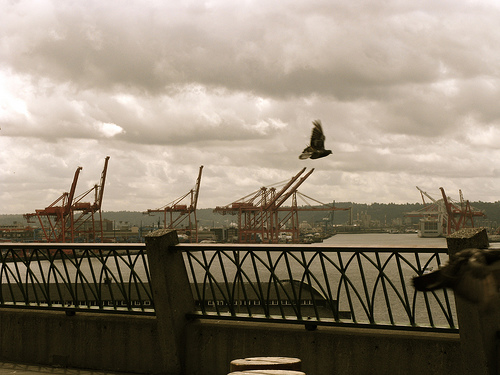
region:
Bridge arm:
[1, 229, 498, 373]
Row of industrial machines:
[4, 153, 495, 257]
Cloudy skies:
[1, 2, 496, 212]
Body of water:
[1, 231, 496, 332]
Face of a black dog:
[414, 245, 498, 307]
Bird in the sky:
[297, 119, 332, 164]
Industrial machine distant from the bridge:
[407, 179, 482, 240]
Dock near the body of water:
[4, 275, 356, 317]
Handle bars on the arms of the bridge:
[2, 243, 462, 335]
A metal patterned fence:
[181, 239, 408, 324]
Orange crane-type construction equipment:
[38, 163, 112, 235]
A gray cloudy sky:
[132, 88, 272, 155]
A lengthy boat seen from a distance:
[338, 210, 429, 237]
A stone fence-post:
[145, 223, 186, 357]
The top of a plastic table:
[222, 356, 314, 372]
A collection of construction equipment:
[172, 190, 359, 236]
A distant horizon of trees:
[330, 196, 415, 218]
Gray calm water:
[337, 234, 409, 246]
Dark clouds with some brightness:
[2, 94, 119, 139]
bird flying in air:
[297, 115, 333, 165]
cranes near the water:
[215, 164, 305, 241]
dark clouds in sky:
[7, 2, 479, 199]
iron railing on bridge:
[3, 235, 498, 330]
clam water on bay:
[25, 230, 498, 331]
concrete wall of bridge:
[0, 305, 499, 372]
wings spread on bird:
[308, 117, 328, 150]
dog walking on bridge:
[409, 247, 499, 370]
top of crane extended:
[94, 153, 115, 209]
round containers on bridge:
[225, 354, 303, 374]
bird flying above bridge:
[299, 119, 331, 166]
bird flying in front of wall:
[410, 241, 499, 313]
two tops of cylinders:
[213, 355, 306, 374]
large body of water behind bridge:
[1, 227, 499, 330]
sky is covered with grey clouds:
[0, 0, 499, 217]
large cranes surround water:
[23, 165, 478, 247]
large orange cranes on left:
[30, 155, 351, 255]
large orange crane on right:
[406, 181, 488, 240]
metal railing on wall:
[3, 239, 499, 335]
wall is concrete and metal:
[3, 227, 496, 374]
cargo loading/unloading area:
[22, 50, 489, 255]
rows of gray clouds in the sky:
[22, 5, 272, 160]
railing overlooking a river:
[0, 225, 205, 351]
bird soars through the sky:
[287, 112, 337, 162]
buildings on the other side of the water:
[325, 210, 441, 230]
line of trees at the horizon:
[355, 190, 425, 210]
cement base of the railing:
[0, 305, 120, 370]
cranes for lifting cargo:
[25, 151, 116, 231]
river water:
[336, 231, 412, 241]